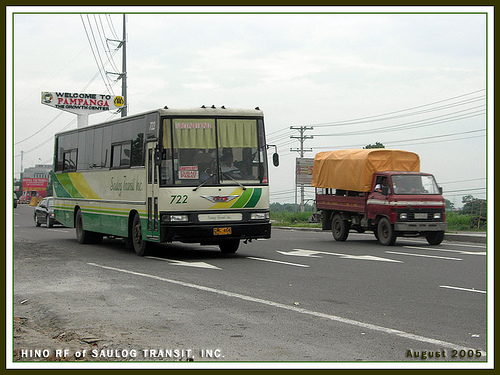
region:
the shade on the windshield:
[164, 116, 259, 147]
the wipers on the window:
[187, 166, 253, 193]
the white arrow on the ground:
[145, 249, 237, 284]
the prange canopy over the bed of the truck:
[307, 149, 422, 192]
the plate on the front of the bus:
[211, 224, 236, 236]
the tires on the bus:
[73, 198, 148, 257]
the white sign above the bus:
[36, 83, 129, 124]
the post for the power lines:
[86, 16, 134, 91]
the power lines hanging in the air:
[309, 85, 488, 147]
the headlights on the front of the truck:
[394, 208, 444, 223]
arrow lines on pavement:
[146, 247, 236, 295]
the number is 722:
[140, 181, 210, 226]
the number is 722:
[155, 179, 203, 213]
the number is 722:
[170, 189, 203, 210]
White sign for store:
[34, 84, 129, 122]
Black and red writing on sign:
[45, 88, 125, 114]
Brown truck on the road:
[302, 132, 454, 266]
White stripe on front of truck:
[360, 184, 457, 224]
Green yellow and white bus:
[43, 103, 282, 258]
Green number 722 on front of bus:
[162, 188, 198, 215]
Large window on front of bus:
[150, 110, 280, 200]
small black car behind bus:
[20, 188, 71, 244]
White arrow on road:
[127, 222, 225, 302]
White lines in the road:
[245, 252, 499, 338]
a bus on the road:
[31, 101, 286, 280]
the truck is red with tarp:
[292, 113, 467, 263]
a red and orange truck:
[314, 149, 444, 250]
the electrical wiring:
[285, 113, 470, 144]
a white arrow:
[151, 251, 218, 276]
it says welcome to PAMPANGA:
[42, 89, 118, 111]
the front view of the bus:
[158, 110, 265, 238]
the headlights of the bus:
[170, 209, 267, 220]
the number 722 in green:
[168, 190, 190, 210]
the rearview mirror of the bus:
[268, 145, 282, 167]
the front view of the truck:
[390, 176, 443, 231]